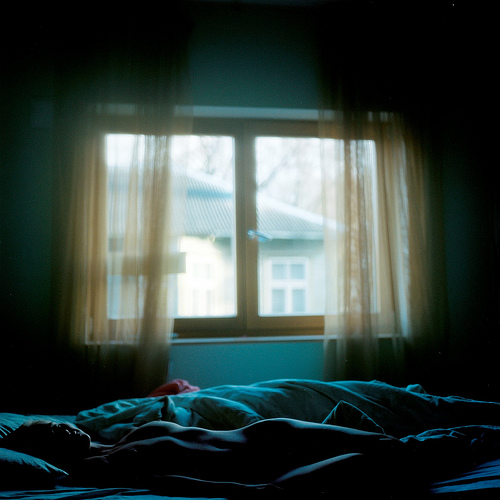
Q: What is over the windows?
A: Curtains.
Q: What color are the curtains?
A: White.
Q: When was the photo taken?
A: Day time.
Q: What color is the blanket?
A: Blue.